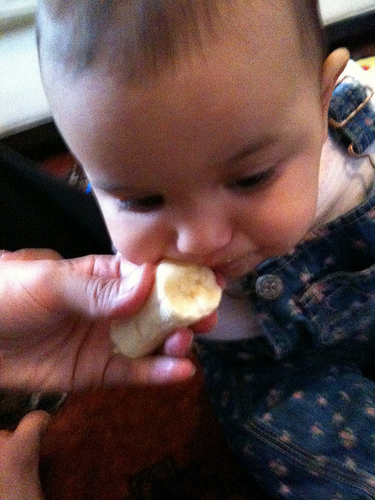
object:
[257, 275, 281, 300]
button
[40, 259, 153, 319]
thumb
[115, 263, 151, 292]
thumbnail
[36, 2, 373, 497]
baby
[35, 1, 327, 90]
hair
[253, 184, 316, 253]
cheek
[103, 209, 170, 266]
cheek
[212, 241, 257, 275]
mouth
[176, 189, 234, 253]
nose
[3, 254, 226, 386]
hand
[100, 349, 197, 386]
finger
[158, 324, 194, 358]
finger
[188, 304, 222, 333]
finger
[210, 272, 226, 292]
finger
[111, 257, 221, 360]
banana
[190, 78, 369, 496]
overalls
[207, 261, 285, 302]
clasp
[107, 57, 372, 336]
shirt